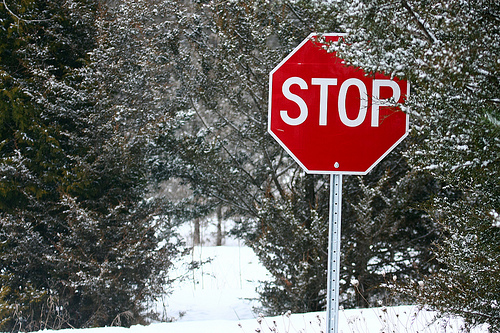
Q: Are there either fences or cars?
A: No, there are no cars or fences.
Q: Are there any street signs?
A: Yes, there is a street sign.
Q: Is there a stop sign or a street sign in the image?
A: Yes, there is a street sign.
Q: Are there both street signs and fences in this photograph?
A: No, there is a street sign but no fences.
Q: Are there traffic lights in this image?
A: No, there are no traffic lights.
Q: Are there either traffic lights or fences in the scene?
A: No, there are no traffic lights or fences.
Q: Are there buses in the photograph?
A: Yes, there is a bus.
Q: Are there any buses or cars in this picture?
A: Yes, there is a bus.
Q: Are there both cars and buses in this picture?
A: No, there is a bus but no cars.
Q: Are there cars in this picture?
A: No, there are no cars.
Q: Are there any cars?
A: No, there are no cars.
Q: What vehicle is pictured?
A: The vehicle is a bus.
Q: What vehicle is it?
A: The vehicle is a bus.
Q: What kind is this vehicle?
A: This is a bus.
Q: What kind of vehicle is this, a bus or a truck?
A: This is a bus.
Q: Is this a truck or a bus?
A: This is a bus.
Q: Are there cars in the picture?
A: No, there are no cars.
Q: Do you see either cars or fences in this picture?
A: No, there are no cars or fences.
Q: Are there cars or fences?
A: No, there are no cars or fences.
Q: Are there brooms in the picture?
A: No, there are no brooms.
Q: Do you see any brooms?
A: No, there are no brooms.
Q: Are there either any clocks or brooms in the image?
A: No, there are no brooms or clocks.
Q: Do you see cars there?
A: No, there are no cars.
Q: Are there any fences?
A: No, there are no fences.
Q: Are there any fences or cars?
A: No, there are no fences or cars.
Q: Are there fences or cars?
A: No, there are no fences or cars.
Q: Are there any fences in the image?
A: No, there are no fences.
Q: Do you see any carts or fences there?
A: No, there are no fences or carts.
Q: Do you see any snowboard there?
A: No, there are no snowboards.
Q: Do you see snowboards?
A: No, there are no snowboards.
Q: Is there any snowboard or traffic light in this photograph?
A: No, there are no snowboards or traffic lights.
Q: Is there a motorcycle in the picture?
A: No, there are no motorcycles.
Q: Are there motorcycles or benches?
A: No, there are no motorcycles or benches.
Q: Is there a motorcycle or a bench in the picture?
A: No, there are no motorcycles or benches.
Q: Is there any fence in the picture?
A: No, there are no fences.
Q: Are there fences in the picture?
A: No, there are no fences.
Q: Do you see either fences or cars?
A: No, there are no fences or cars.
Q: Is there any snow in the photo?
A: Yes, there is snow.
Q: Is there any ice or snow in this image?
A: Yes, there is snow.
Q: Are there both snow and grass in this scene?
A: No, there is snow but no grass.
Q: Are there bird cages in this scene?
A: No, there are no bird cages.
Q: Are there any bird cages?
A: No, there are no bird cages.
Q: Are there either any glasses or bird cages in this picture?
A: No, there are no bird cages or glasses.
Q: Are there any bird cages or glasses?
A: No, there are no bird cages or glasses.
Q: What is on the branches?
A: The snow is on the branches.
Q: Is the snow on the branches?
A: Yes, the snow is on the branches.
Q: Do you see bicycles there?
A: No, there are no bicycles.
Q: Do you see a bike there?
A: No, there are no bikes.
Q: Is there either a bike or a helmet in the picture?
A: No, there are no bikes or helmets.